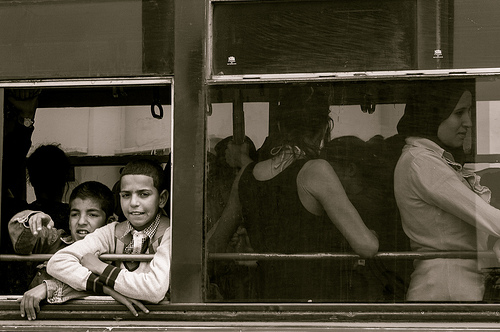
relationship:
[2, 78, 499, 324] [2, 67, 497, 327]
people in bus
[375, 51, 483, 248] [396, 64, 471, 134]
lady in covering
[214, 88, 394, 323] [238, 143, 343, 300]
lady in tank top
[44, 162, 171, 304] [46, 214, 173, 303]
young boy in sweater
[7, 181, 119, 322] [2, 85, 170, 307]
boy in window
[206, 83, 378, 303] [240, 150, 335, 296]
lady in tank top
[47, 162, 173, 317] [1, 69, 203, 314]
boy in window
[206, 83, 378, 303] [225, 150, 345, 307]
lady in tank top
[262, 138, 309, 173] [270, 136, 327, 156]
tie in woman's neck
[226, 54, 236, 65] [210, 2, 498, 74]
logo in window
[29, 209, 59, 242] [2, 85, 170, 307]
hand in window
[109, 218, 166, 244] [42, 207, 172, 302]
collar in shirt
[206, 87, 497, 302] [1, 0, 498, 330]
window in bus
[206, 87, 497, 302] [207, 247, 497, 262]
window in steel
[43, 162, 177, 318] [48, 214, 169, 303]
boy in shirt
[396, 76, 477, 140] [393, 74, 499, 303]
black scarf in woman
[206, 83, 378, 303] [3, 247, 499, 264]
lady in rail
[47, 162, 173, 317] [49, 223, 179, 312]
boy wearing sweater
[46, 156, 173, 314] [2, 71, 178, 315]
boy looking out window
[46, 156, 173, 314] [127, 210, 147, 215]
boy biting lower lip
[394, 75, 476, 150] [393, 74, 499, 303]
head on woman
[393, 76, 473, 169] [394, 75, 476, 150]
scarf on head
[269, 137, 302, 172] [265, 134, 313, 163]
tie on neck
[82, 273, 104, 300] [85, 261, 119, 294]
stripes on cuff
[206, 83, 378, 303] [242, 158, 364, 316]
lady wearing dress